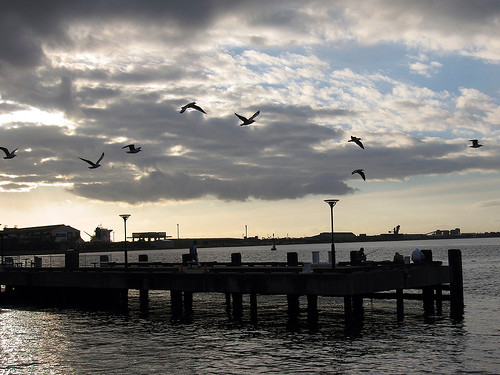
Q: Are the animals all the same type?
A: Yes, all the animals are birds.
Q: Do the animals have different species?
A: No, all the animals are birds.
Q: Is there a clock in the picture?
A: No, there are no clocks.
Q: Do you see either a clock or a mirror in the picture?
A: No, there are no clocks or mirrors.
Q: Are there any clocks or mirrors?
A: No, there are no clocks or mirrors.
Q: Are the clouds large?
A: Yes, the clouds are large.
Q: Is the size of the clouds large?
A: Yes, the clouds are large.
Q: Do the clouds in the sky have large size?
A: Yes, the clouds are large.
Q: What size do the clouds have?
A: The clouds have large size.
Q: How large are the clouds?
A: The clouds are large.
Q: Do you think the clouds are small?
A: No, the clouds are large.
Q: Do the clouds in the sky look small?
A: No, the clouds are large.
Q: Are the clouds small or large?
A: The clouds are large.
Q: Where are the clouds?
A: The clouds are in the sky.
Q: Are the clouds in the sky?
A: Yes, the clouds are in the sky.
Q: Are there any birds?
A: Yes, there is a bird.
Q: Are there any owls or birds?
A: Yes, there is a bird.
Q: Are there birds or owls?
A: Yes, there is a bird.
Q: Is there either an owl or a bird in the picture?
A: Yes, there is a bird.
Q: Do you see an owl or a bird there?
A: Yes, there is a bird.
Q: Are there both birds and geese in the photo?
A: No, there is a bird but no geese.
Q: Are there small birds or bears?
A: Yes, there is a small bird.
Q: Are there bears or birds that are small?
A: Yes, the bird is small.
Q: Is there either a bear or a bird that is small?
A: Yes, the bird is small.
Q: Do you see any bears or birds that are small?
A: Yes, the bird is small.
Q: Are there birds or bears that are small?
A: Yes, the bird is small.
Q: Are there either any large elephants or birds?
A: Yes, there is a large bird.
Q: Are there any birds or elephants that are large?
A: Yes, the bird is large.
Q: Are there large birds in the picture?
A: Yes, there is a large bird.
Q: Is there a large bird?
A: Yes, there is a large bird.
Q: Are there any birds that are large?
A: Yes, there is a bird that is large.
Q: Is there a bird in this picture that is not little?
A: Yes, there is a large bird.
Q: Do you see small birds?
A: Yes, there is a small bird.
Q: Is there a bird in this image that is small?
A: Yes, there is a bird that is small.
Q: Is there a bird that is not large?
A: Yes, there is a small bird.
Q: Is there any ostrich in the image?
A: No, there are no ostriches.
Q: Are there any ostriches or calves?
A: No, there are no ostriches or calves.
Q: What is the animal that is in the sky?
A: The animal is a bird.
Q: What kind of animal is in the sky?
A: The animal is a bird.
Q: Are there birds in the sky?
A: Yes, there is a bird in the sky.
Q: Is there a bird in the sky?
A: Yes, there is a bird in the sky.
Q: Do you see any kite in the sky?
A: No, there is a bird in the sky.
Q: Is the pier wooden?
A: Yes, the pier is wooden.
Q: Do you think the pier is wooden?
A: Yes, the pier is wooden.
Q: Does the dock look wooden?
A: Yes, the dock is wooden.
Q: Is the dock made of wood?
A: Yes, the dock is made of wood.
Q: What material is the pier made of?
A: The pier is made of wood.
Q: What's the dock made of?
A: The pier is made of wood.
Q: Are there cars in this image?
A: No, there are no cars.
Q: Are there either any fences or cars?
A: No, there are no cars or fences.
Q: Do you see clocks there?
A: No, there are no clocks.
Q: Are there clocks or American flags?
A: No, there are no clocks or American flags.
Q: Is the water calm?
A: Yes, the water is calm.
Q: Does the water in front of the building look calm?
A: Yes, the water is calm.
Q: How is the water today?
A: The water is calm.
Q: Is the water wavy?
A: No, the water is calm.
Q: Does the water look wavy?
A: No, the water is calm.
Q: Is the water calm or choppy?
A: The water is calm.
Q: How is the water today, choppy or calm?
A: The water is calm.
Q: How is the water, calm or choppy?
A: The water is calm.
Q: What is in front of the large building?
A: The water is in front of the building.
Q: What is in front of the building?
A: The water is in front of the building.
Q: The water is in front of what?
A: The water is in front of the building.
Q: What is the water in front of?
A: The water is in front of the building.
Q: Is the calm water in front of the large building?
A: Yes, the water is in front of the building.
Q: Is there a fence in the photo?
A: No, there are no fences.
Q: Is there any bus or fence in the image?
A: No, there are no fences or buses.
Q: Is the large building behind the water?
A: Yes, the building is behind the water.